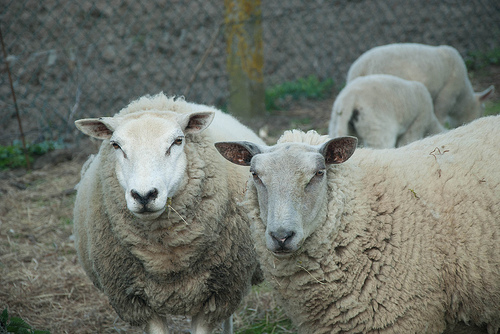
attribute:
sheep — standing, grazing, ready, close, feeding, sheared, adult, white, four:
[384, 198, 449, 247]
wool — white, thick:
[189, 165, 228, 226]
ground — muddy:
[67, 47, 106, 72]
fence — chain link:
[42, 23, 187, 43]